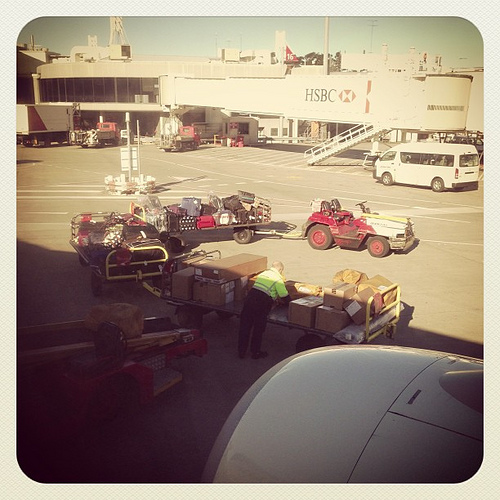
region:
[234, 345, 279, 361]
Man wearing shoes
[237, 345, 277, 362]
Man is wearing shoes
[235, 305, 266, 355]
Man wearing pants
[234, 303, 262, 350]
Man is wearing pants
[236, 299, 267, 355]
Man wearing black pants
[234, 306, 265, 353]
Man is wearing black pants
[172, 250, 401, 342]
Boxes on a cart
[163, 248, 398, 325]
Boxes are on a cart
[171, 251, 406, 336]
Cardboard boxes on a cart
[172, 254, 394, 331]
Cardboard boxes are on a cart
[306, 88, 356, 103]
bank advertisement on the wall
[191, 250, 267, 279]
a large cardboard box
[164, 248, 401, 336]
a cart of cardboard boxes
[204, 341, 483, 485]
a plane engine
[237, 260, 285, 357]
man is wearing a yellow vest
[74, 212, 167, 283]
a cart full of luggage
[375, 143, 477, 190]
a white transport van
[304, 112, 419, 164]
staircase to a plane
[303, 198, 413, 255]
cart moving vehicle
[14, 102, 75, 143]
a large white box truck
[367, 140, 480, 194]
a white van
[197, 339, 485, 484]
an airplane engine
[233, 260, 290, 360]
a man in reflective gear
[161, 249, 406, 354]
a trolley full of cardboard packages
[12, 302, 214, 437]
a portable conveyor belt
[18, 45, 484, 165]
an airport terminal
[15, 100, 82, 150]
a white and red truck trailor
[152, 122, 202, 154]
a small red truck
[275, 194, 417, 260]
a small red and white vehicle with hitch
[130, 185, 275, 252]
a flatbed vehicle full of passenger baggage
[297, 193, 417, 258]
it is a truck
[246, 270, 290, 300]
man wearing green color shirt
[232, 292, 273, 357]
man wearing black pant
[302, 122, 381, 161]
it is a ladder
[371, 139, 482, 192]
it is a white color van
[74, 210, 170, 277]
it is goods carrier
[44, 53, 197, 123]
it is a building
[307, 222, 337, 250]
it is truck tire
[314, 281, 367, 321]
it is brown color box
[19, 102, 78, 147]
it is truck container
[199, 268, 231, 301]
Boxes arranged on a cart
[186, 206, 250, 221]
Suitcases stacked on a cart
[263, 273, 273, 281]
Man in a yellow jacket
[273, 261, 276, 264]
Back of head bald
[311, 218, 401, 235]
A towing vehicle hitched to cart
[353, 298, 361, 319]
Box laid at an angle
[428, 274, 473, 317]
Light shining on the ground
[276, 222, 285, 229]
Shadow cast by cart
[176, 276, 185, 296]
Shadow on a box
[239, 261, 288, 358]
the man is standing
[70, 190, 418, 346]
the vehicle pulling the long trailer train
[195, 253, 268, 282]
the box is brown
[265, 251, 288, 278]
the head of a man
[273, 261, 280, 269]
the hair of a man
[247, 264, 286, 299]
the shirt of a man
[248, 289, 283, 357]
the leg of a man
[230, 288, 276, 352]
the pants of a man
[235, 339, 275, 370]
the shoes of a man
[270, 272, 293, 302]
the arm of a man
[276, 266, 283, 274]
the ear of a man